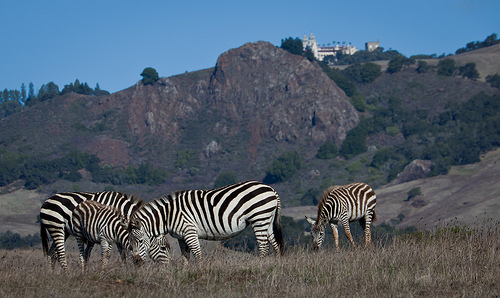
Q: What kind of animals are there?
A: Zebras.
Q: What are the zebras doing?
A: Eating.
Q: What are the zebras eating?
A: Grass.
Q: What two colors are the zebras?
A: Black and white.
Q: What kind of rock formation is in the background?
A: A cliff.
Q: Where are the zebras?
A: On the ground.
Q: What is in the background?
A: A structure.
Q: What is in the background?
A: Hills.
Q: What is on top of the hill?
A: Building.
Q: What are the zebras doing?
A: Eating.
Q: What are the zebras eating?
A: Grass.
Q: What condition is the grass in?
A: Brown.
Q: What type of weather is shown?
A: Clear.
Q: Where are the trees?
A: Hill.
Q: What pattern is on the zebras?
A: Stripes.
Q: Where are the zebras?
A: Valley.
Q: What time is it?
A: Afternoon.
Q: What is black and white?
A: Zebras.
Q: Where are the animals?
A: Outside somewhere.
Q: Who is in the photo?
A: No people.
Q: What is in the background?
A: A structure.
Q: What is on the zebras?
A: Stripes.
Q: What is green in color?
A: Trees.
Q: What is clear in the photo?
A: The sky.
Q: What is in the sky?
A: Nothing.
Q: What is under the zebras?
A: Grass.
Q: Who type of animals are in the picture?
A: Zebras.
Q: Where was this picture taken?
A: In a field.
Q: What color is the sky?
A: Blue.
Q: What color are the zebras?
A: Black and white.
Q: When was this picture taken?
A: During the day.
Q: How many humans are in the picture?
A: Zero.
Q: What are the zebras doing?
A: Eating grass.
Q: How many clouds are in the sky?
A: Zero.